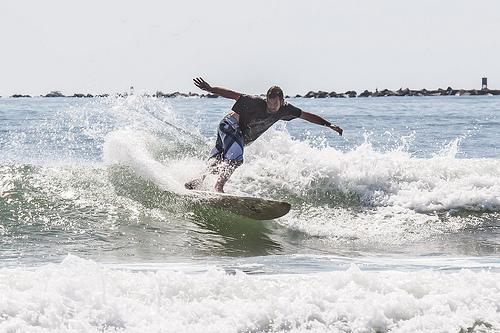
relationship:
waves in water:
[85, 98, 498, 211] [1, 97, 500, 333]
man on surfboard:
[184, 76, 342, 193] [186, 189, 293, 220]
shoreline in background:
[0, 77, 499, 97] [1, 0, 499, 96]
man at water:
[184, 76, 342, 193] [1, 96, 500, 333]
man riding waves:
[184, 76, 342, 193] [85, 98, 498, 211]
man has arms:
[184, 76, 342, 193] [192, 76, 343, 136]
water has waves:
[1, 96, 500, 333] [85, 98, 498, 211]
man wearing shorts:
[184, 76, 342, 193] [207, 115, 245, 162]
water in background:
[1, 96, 500, 333] [0, 1, 499, 159]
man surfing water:
[184, 76, 342, 193] [1, 96, 500, 333]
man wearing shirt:
[184, 76, 342, 193] [231, 93, 301, 146]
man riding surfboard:
[184, 76, 342, 193] [186, 189, 293, 220]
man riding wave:
[184, 76, 342, 193] [103, 94, 375, 200]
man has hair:
[184, 76, 342, 193] [266, 86, 285, 100]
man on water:
[184, 76, 342, 193] [1, 97, 500, 333]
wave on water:
[103, 94, 375, 200] [1, 96, 500, 333]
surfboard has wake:
[186, 189, 293, 220] [151, 139, 206, 192]